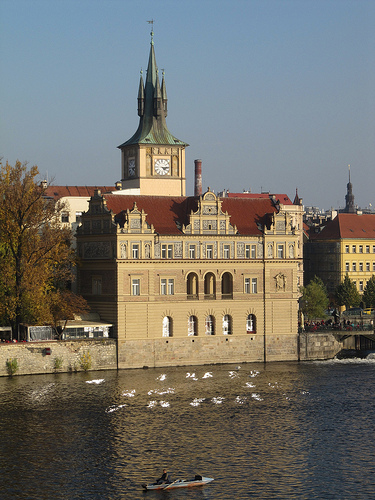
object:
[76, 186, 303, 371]
brick building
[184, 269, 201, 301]
arched openings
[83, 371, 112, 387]
objects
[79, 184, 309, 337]
building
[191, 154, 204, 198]
chimney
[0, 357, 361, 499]
water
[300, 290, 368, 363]
bridge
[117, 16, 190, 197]
clock tower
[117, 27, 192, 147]
roof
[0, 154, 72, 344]
tree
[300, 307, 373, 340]
people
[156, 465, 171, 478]
person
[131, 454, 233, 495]
boat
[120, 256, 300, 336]
wall